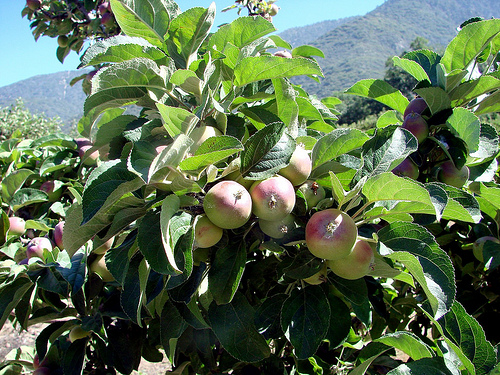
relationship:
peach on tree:
[301, 206, 361, 260] [97, 49, 400, 281]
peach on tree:
[322, 232, 381, 281] [97, 49, 400, 281]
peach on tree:
[272, 141, 314, 187] [97, 49, 400, 281]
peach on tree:
[246, 172, 293, 224] [97, 49, 400, 281]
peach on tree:
[185, 213, 221, 252] [97, 49, 400, 281]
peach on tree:
[303, 207, 356, 263] [3, 2, 495, 372]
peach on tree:
[330, 236, 378, 283] [3, 2, 495, 372]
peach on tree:
[280, 144, 309, 185] [3, 2, 495, 372]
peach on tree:
[252, 173, 297, 223] [3, 2, 495, 372]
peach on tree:
[203, 175, 251, 232] [3, 2, 495, 372]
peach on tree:
[192, 215, 220, 250] [3, 2, 495, 372]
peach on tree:
[308, 203, 354, 257] [3, 2, 495, 372]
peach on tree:
[252, 174, 299, 216] [3, 2, 495, 372]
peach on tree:
[198, 170, 258, 227] [3, 2, 495, 372]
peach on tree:
[187, 215, 222, 246] [3, 2, 495, 372]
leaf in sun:
[235, 56, 329, 91] [173, 5, 497, 288]